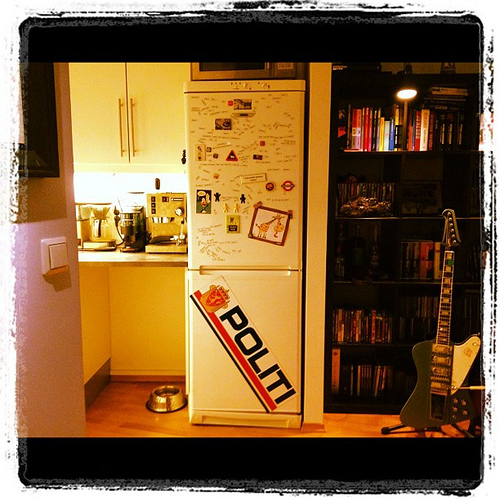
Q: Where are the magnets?
A: On the refrigerator.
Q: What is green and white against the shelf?
A: The guitar.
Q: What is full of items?
A: A bookcase.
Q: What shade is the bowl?
A: Silver.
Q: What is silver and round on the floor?
A: The bowl.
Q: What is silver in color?
A: The bowl.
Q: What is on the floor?
A: The bowl.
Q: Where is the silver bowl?
A: On the ground.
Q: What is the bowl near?
A: The fridge.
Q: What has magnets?
A: Fridge.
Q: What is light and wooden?
A: Door.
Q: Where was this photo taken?
A: In a kitchen.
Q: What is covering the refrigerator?
A: Writing.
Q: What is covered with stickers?
A: Fridge.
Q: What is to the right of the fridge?
A: Bookshelf.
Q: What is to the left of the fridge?
A: Cabinets.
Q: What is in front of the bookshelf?
A: Guitar.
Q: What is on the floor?
A: Dog bowl.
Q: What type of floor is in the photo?
A: Wood floor.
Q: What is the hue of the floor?
A: Brown.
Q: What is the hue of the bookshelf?
A: Black.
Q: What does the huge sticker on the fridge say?
A: Politi.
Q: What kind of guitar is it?
A: An electric guitar.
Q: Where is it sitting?
A: On a stand.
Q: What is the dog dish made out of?
A: Stainless steel.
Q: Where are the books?
A: In the bookshelf.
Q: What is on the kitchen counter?
A: Appliances.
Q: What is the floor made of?
A: Wood.